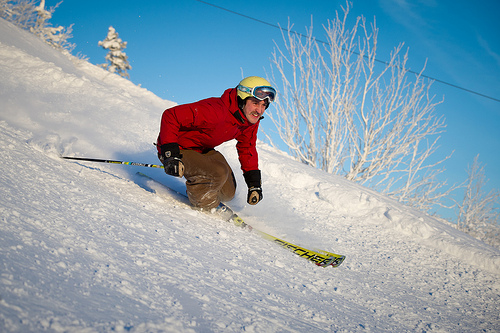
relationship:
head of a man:
[237, 74, 279, 124] [156, 76, 278, 214]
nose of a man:
[256, 105, 264, 117] [156, 76, 278, 214]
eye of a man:
[251, 101, 260, 106] [156, 76, 278, 214]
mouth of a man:
[253, 111, 259, 117] [156, 76, 278, 214]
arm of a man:
[155, 100, 215, 174] [156, 76, 278, 214]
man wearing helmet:
[156, 76, 278, 214] [236, 75, 276, 107]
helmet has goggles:
[236, 75, 276, 107] [252, 85, 277, 103]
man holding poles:
[156, 76, 278, 214] [59, 155, 185, 176]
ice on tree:
[99, 26, 131, 76] [103, 27, 131, 74]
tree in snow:
[103, 27, 131, 74] [101, 27, 133, 78]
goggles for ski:
[252, 85, 277, 103] [1, 0, 499, 332]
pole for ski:
[59, 155, 185, 176] [94, 165, 341, 265]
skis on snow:
[135, 169, 347, 269] [1, 17, 499, 329]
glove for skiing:
[244, 172, 268, 205] [1, 3, 498, 331]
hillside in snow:
[1, 15, 500, 332] [1, 17, 499, 329]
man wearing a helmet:
[156, 76, 278, 214] [236, 75, 276, 107]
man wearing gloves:
[156, 76, 278, 214] [159, 142, 186, 177]